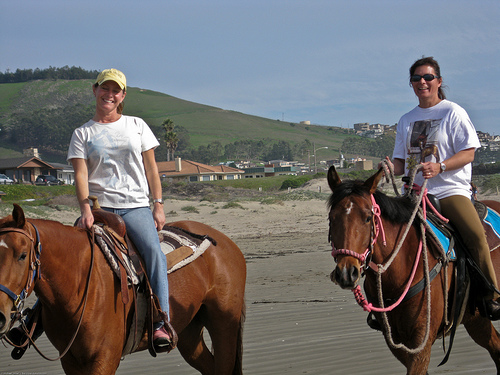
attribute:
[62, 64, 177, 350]
woman — smiling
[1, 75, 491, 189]
hill — long, sloping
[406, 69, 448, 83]
glasses — black, sun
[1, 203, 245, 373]
brown horse — short haired brown 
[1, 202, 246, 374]
horse — brown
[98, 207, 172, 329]
pants — DENIM, LIGHT BLUE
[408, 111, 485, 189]
tee shirt — WHITE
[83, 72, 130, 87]
cap — yellow 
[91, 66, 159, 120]
cap — PALE YELLOW, BASEBALL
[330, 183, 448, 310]
harness — pink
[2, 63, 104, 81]
trees — dark green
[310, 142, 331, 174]
street light — distant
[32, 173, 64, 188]
black car — parked, subaru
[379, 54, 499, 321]
woman — smiling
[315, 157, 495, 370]
brown horse — SHORT HAIRED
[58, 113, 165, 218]
tee shirt — white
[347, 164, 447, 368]
reins — pink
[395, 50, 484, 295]
woman — smiling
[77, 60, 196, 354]
woman — smiling